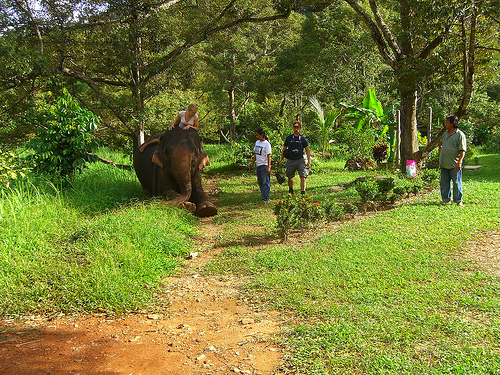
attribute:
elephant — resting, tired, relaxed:
[131, 124, 223, 221]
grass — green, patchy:
[0, 141, 500, 375]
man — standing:
[436, 114, 471, 209]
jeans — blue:
[438, 164, 465, 204]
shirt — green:
[435, 127, 470, 171]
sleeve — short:
[436, 130, 450, 144]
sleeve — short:
[455, 132, 470, 154]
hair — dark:
[444, 114, 460, 133]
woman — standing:
[244, 126, 277, 205]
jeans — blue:
[255, 164, 273, 201]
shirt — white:
[250, 139, 274, 170]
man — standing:
[277, 119, 315, 202]